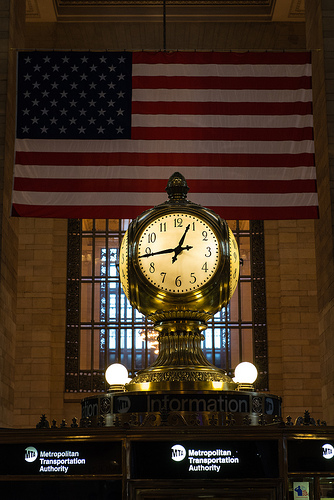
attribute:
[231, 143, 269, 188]
stripes — red and white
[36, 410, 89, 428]
objects — small, metal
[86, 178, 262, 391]
clock — gold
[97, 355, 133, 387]
light — globe shaped, globe, round, small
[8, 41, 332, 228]
flag — usa, United States, red, white, large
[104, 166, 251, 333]
clock — large, black numbers, shiny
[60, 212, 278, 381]
window — tall, large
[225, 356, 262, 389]
light — white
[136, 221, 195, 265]
hands — black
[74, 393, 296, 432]
letters — white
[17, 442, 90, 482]
letters — white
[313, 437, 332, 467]
sticker — blue, red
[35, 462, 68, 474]
letters — white